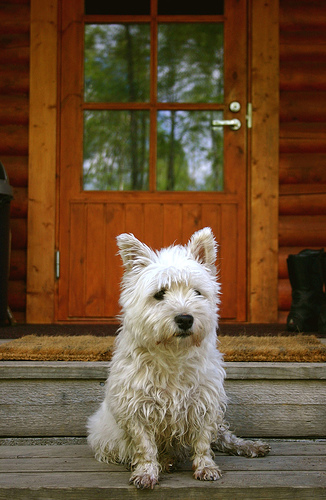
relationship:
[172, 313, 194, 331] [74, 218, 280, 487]
nose of dog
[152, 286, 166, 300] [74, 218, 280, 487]
eye of dog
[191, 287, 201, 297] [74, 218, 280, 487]
eye of dog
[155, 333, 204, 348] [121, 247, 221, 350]
fur on end face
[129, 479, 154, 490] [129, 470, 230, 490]
claws on claws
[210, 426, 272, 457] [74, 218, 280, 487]
leg of dog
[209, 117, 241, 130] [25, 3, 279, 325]
handle on door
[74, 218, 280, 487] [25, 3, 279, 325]
dog waiting in front door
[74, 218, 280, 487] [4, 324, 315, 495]
dog sitting on porch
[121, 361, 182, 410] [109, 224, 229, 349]
fur on face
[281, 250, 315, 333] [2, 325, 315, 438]
boots on porch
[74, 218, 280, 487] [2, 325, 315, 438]
dog on porch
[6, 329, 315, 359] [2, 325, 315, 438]
mat on porch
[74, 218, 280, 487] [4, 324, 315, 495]
dog waiting porch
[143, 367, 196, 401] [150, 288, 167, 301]
fur hanging eyes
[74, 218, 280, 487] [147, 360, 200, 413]
dog hidden fur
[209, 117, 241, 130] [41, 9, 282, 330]
handle on door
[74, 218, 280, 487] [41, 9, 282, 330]
dog sitting door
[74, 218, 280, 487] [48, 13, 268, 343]
dog sitting door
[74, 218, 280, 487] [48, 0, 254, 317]
dog sitting door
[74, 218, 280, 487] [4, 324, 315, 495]
dog sitting porch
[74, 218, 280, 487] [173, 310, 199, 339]
dog has nose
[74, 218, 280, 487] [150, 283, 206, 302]
dog has eyes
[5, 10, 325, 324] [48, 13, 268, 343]
building has door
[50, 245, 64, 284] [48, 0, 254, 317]
hinge on door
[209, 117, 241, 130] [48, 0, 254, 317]
handle on door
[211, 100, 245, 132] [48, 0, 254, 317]
lock on door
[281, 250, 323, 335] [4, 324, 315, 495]
boots on porch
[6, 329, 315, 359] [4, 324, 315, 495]
mat on porch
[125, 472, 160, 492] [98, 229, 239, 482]
paw of dog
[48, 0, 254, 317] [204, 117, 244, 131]
door has handle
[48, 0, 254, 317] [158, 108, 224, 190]
door has window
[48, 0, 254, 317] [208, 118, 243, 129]
door has handle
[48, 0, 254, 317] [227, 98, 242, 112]
door has lock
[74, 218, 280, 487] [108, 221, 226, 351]
dog has head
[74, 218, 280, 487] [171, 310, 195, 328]
dog has nose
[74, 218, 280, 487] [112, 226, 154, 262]
dog has ear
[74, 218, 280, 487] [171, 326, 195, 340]
dog has mouth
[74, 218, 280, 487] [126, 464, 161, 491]
dog has paw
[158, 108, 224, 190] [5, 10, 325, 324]
window on building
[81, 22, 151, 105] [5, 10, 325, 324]
window on building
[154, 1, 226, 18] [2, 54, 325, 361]
window on building